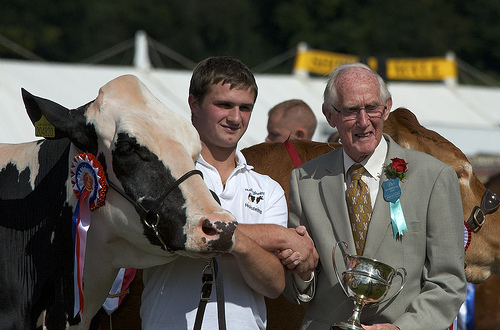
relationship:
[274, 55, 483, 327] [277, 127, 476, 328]
man wearing suit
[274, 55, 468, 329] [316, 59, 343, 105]
man has hair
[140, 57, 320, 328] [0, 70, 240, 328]
boy next to cow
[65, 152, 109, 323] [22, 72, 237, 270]
ribbon on head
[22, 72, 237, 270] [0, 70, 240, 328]
head on cow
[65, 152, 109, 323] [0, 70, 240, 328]
ribbon on cow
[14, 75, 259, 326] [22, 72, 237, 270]
cow has head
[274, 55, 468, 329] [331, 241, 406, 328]
man holding trophy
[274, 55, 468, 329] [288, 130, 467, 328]
man wearing suit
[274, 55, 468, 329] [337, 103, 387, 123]
man wearing eyeglasses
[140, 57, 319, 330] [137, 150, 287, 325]
boy wearing shirt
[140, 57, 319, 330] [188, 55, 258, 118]
boy has hair